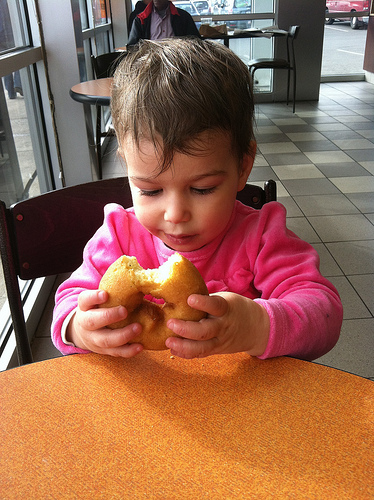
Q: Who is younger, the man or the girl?
A: The girl is younger than the man.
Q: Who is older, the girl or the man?
A: The man is older than the girl.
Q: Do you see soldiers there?
A: No, there are no soldiers.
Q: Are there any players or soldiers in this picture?
A: No, there are no soldiers or players.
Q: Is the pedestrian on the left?
A: Yes, the pedestrian is on the left of the image.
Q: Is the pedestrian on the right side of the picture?
A: No, the pedestrian is on the left of the image.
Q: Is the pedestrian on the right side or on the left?
A: The pedestrian is on the left of the image.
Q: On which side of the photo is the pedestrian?
A: The pedestrian is on the left of the image.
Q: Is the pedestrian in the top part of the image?
A: Yes, the pedestrian is in the top of the image.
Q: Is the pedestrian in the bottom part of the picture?
A: No, the pedestrian is in the top of the image.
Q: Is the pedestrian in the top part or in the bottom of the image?
A: The pedestrian is in the top of the image.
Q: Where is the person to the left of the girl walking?
A: The pedestrian is walking on the sidewalk.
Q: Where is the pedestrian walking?
A: The pedestrian is walking on the sidewalk.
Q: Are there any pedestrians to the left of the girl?
A: Yes, there is a pedestrian to the left of the girl.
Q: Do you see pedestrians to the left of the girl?
A: Yes, there is a pedestrian to the left of the girl.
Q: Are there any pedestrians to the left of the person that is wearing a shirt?
A: Yes, there is a pedestrian to the left of the girl.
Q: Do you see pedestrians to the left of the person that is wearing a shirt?
A: Yes, there is a pedestrian to the left of the girl.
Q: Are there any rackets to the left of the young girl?
A: No, there is a pedestrian to the left of the girl.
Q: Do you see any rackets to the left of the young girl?
A: No, there is a pedestrian to the left of the girl.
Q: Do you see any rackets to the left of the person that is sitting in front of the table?
A: No, there is a pedestrian to the left of the girl.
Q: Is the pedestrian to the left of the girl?
A: Yes, the pedestrian is to the left of the girl.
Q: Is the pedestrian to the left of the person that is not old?
A: Yes, the pedestrian is to the left of the girl.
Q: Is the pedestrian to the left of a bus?
A: No, the pedestrian is to the left of the girl.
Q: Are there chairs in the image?
A: Yes, there is a chair.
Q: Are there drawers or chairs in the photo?
A: Yes, there is a chair.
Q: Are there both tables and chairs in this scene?
A: Yes, there are both a chair and a table.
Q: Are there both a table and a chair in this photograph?
A: Yes, there are both a chair and a table.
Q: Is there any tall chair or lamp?
A: Yes, there is a tall chair.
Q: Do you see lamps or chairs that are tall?
A: Yes, the chair is tall.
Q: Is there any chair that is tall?
A: Yes, there is a tall chair.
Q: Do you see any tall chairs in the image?
A: Yes, there is a tall chair.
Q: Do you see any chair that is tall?
A: Yes, there is a chair that is tall.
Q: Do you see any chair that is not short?
A: Yes, there is a tall chair.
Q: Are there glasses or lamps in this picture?
A: No, there are no glasses or lamps.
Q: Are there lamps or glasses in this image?
A: No, there are no glasses or lamps.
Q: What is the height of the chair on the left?
A: The chair is tall.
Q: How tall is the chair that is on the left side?
A: The chair is tall.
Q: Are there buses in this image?
A: No, there are no buses.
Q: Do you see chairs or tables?
A: Yes, there is a chair.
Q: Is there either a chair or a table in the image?
A: Yes, there is a chair.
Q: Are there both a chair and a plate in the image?
A: No, there is a chair but no plates.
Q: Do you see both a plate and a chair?
A: No, there is a chair but no plates.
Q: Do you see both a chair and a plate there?
A: No, there is a chair but no plates.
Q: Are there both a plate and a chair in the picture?
A: No, there is a chair but no plates.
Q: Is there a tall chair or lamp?
A: Yes, there is a tall chair.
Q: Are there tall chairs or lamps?
A: Yes, there is a tall chair.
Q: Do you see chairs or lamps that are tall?
A: Yes, the chair is tall.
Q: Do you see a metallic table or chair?
A: Yes, there is a metal chair.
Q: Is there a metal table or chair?
A: Yes, there is a metal chair.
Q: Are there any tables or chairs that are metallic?
A: Yes, the chair is metallic.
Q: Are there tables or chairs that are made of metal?
A: Yes, the chair is made of metal.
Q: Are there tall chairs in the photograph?
A: Yes, there is a tall chair.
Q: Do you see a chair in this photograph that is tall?
A: Yes, there is a chair that is tall.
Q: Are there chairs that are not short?
A: Yes, there is a tall chair.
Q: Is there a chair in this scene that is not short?
A: Yes, there is a tall chair.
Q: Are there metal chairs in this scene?
A: Yes, there is a metal chair.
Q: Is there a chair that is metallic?
A: Yes, there is a chair that is metallic.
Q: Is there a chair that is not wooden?
A: Yes, there is a metallic chair.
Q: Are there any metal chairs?
A: Yes, there is a chair that is made of metal.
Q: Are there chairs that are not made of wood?
A: Yes, there is a chair that is made of metal.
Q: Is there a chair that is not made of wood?
A: Yes, there is a chair that is made of metal.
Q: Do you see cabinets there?
A: No, there are no cabinets.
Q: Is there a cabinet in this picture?
A: No, there are no cabinets.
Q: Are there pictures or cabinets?
A: No, there are no cabinets or pictures.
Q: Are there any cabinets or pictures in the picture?
A: No, there are no cabinets or pictures.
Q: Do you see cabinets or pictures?
A: No, there are no cabinets or pictures.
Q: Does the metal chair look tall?
A: Yes, the chair is tall.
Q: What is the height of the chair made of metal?
A: The chair is tall.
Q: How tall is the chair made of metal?
A: The chair is tall.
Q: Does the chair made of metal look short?
A: No, the chair is tall.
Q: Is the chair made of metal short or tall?
A: The chair is tall.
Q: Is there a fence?
A: No, there are no fences.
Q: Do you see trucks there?
A: Yes, there is a truck.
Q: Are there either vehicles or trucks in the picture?
A: Yes, there is a truck.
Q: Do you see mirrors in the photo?
A: No, there are no mirrors.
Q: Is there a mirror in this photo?
A: No, there are no mirrors.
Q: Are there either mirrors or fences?
A: No, there are no mirrors or fences.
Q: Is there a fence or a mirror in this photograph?
A: No, there are no mirrors or fences.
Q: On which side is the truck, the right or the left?
A: The truck is on the right of the image.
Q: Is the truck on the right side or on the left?
A: The truck is on the right of the image.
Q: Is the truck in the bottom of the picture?
A: No, the truck is in the top of the image.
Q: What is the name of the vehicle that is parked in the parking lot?
A: The vehicle is a truck.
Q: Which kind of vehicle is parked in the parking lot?
A: The vehicle is a truck.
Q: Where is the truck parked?
A: The truck is parked in the parking lot.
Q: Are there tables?
A: Yes, there is a table.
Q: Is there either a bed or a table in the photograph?
A: Yes, there is a table.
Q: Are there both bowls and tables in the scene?
A: No, there is a table but no bowls.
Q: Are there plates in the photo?
A: No, there are no plates.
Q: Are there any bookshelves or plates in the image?
A: No, there are no plates or bookshelves.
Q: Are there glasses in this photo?
A: No, there are no glasses.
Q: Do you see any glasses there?
A: No, there are no glasses.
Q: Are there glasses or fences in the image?
A: No, there are no glasses or fences.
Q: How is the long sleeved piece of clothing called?
A: The clothing item is a shirt.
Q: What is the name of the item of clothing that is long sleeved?
A: The clothing item is a shirt.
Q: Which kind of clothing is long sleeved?
A: The clothing is a shirt.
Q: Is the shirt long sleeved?
A: Yes, the shirt is long sleeved.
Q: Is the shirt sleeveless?
A: No, the shirt is long sleeved.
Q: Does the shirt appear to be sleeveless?
A: No, the shirt is long sleeved.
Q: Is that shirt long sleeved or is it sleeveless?
A: The shirt is long sleeved.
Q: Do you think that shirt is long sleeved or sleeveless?
A: The shirt is long sleeved.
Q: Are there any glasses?
A: No, there are no glasses.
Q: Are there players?
A: No, there are no players.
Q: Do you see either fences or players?
A: No, there are no players or fences.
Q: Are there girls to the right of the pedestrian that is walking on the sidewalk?
A: Yes, there is a girl to the right of the pedestrian.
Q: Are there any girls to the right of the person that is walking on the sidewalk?
A: Yes, there is a girl to the right of the pedestrian.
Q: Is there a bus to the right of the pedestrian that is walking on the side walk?
A: No, there is a girl to the right of the pedestrian.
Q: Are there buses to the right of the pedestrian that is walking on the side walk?
A: No, there is a girl to the right of the pedestrian.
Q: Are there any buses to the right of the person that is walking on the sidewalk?
A: No, there is a girl to the right of the pedestrian.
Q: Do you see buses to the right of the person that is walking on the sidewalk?
A: No, there is a girl to the right of the pedestrian.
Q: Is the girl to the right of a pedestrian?
A: Yes, the girl is to the right of a pedestrian.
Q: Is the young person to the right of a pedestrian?
A: Yes, the girl is to the right of a pedestrian.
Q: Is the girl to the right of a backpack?
A: No, the girl is to the right of a pedestrian.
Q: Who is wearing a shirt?
A: The girl is wearing a shirt.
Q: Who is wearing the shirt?
A: The girl is wearing a shirt.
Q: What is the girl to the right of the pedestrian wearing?
A: The girl is wearing a shirt.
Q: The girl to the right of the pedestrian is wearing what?
A: The girl is wearing a shirt.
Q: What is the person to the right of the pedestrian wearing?
A: The girl is wearing a shirt.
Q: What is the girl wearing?
A: The girl is wearing a shirt.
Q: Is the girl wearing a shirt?
A: Yes, the girl is wearing a shirt.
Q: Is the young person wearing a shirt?
A: Yes, the girl is wearing a shirt.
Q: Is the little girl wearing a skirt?
A: No, the girl is wearing a shirt.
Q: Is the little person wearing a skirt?
A: No, the girl is wearing a shirt.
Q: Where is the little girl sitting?
A: The girl is sitting at the table.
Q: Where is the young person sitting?
A: The girl is sitting at the table.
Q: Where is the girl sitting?
A: The girl is sitting at the table.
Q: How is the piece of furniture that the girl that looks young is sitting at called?
A: The piece of furniture is a table.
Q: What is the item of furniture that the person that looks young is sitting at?
A: The piece of furniture is a table.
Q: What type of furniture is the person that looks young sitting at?
A: The girl is sitting at the table.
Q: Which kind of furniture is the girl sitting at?
A: The girl is sitting at the table.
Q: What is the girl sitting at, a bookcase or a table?
A: The girl is sitting at a table.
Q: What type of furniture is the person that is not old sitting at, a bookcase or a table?
A: The girl is sitting at a table.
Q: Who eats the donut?
A: The girl eats the donut.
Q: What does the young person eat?
A: The girl eats a doughnut.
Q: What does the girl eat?
A: The girl eats a doughnut.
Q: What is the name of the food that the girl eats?
A: The food is a donut.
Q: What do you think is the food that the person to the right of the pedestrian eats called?
A: The food is a donut.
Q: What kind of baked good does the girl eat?
A: The girl eats a doughnut.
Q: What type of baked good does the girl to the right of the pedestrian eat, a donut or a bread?
A: The girl eats a donut.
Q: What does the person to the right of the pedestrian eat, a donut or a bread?
A: The girl eats a donut.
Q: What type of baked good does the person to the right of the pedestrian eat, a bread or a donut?
A: The girl eats a donut.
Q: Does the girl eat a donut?
A: Yes, the girl eats a donut.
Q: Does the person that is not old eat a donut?
A: Yes, the girl eats a donut.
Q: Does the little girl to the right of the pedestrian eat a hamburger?
A: No, the girl eats a donut.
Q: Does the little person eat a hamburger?
A: No, the girl eats a donut.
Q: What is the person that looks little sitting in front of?
A: The girl is sitting in front of the table.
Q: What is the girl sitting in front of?
A: The girl is sitting in front of the table.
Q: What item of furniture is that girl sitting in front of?
A: The girl is sitting in front of the table.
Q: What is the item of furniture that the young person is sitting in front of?
A: The piece of furniture is a table.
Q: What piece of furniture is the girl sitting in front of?
A: The girl is sitting in front of the table.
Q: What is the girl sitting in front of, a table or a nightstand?
A: The girl is sitting in front of a table.